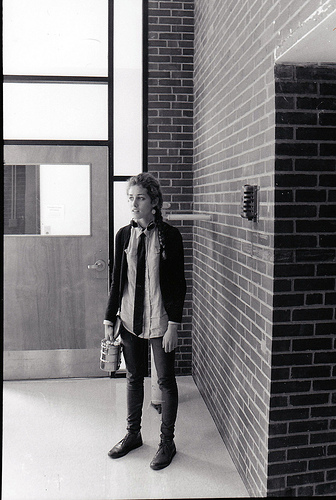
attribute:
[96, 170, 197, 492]
girl — standing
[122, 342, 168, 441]
jeans — skinny, black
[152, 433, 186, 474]
boot — dark, black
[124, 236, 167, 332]
shirt — untucked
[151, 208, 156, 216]
earring — large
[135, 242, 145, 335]
tie — black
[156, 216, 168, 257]
braid — long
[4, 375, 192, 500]
floor — white